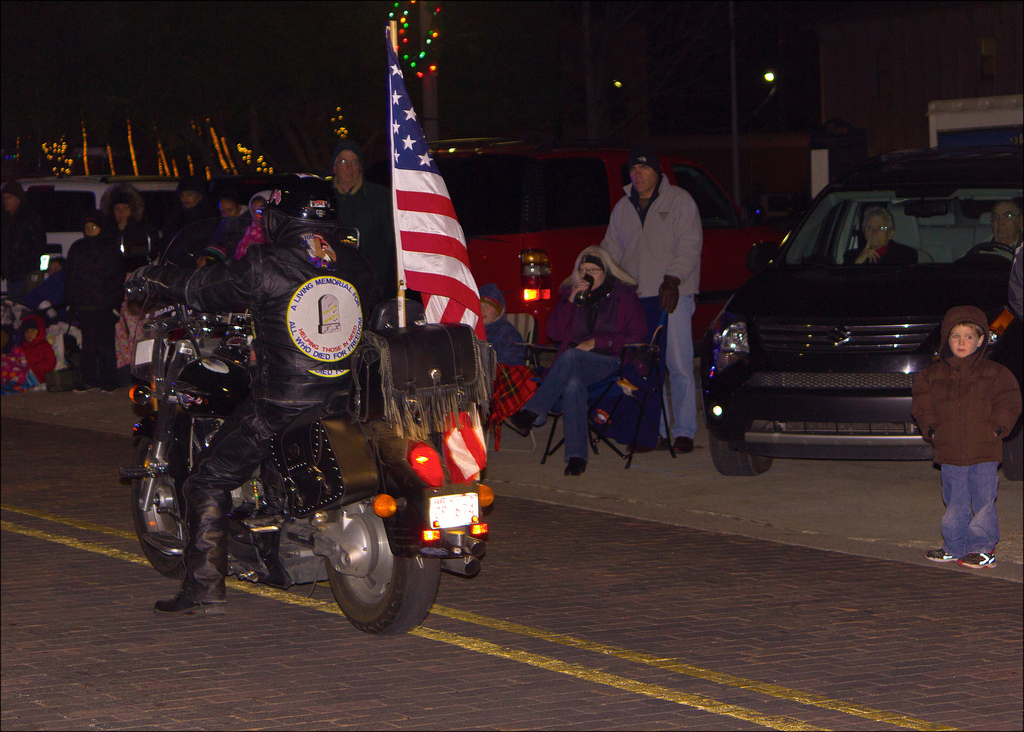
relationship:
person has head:
[581, 134, 723, 356] [599, 154, 712, 204]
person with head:
[581, 134, 723, 356] [599, 154, 712, 204]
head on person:
[599, 154, 712, 204] [581, 134, 723, 356]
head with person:
[599, 154, 712, 204] [581, 134, 723, 356]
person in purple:
[506, 246, 651, 477] [565, 271, 625, 327]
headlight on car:
[497, 273, 557, 319] [441, 156, 630, 301]